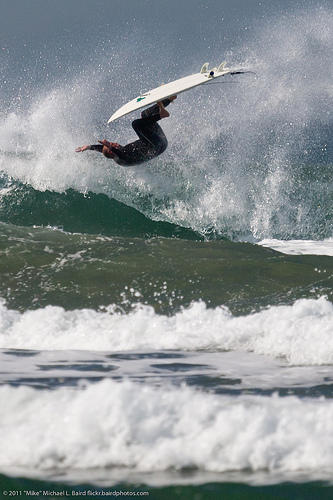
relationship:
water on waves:
[0, 0, 333, 500] [177, 411, 269, 469]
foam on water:
[0, 237, 333, 476] [68, 194, 263, 287]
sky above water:
[0, 1, 331, 123] [0, 112, 330, 380]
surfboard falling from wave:
[107, 61, 250, 125] [0, 1, 333, 238]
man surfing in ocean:
[75, 94, 178, 167] [0, 0, 332, 498]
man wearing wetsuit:
[75, 94, 178, 167] [87, 96, 170, 168]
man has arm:
[75, 94, 178, 167] [99, 137, 128, 163]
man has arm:
[75, 94, 178, 167] [74, 142, 104, 152]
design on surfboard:
[132, 89, 148, 104] [110, 31, 259, 148]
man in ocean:
[75, 94, 177, 165] [0, 0, 332, 498]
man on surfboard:
[75, 94, 178, 167] [102, 56, 258, 125]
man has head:
[75, 94, 178, 167] [98, 139, 122, 159]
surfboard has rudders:
[107, 60, 259, 125] [116, 54, 262, 108]